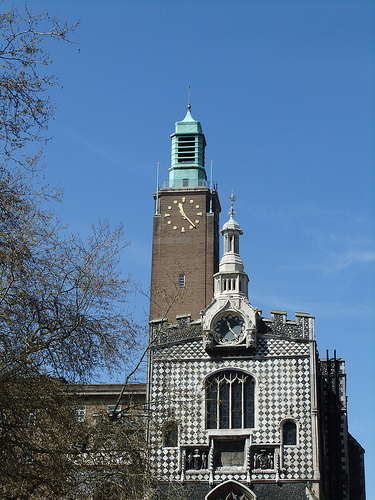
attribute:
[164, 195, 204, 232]
clock — large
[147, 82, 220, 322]
building — brick, brown, tall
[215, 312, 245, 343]
clock — blue, round, large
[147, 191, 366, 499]
building — gray, white, checkered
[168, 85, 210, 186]
tower — teal, green, blue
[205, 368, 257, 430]
window — large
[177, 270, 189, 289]
window — small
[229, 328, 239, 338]
hand — white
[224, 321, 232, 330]
hand — white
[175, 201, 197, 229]
hands — white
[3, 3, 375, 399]
sky — blue, bright blue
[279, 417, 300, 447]
window — arched, small, rounded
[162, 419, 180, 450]
window — arched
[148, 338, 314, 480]
wall — black, white, checkered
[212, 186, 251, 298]
steeple — white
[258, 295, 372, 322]
cloud — white, thin